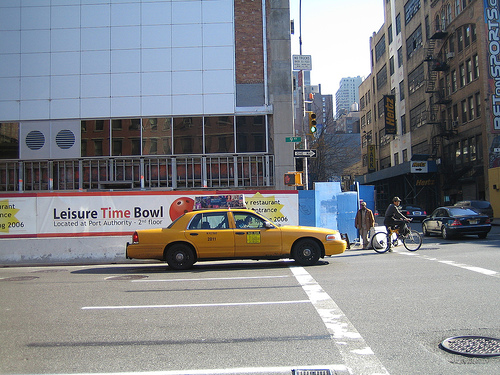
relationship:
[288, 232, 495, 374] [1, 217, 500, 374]
crosswalk on city street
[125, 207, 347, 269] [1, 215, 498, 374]
cab driving down city street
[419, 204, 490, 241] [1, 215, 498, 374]
car driving down city street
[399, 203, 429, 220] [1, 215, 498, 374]
car driving down city street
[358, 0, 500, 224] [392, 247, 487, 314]
building on city street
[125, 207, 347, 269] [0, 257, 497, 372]
cab on street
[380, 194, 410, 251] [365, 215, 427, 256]
man riding bicycle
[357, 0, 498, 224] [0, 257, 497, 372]
building beside street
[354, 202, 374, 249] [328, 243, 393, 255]
man standing on corner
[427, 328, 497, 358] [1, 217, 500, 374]
manhole on city street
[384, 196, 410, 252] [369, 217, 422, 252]
man on bicycle